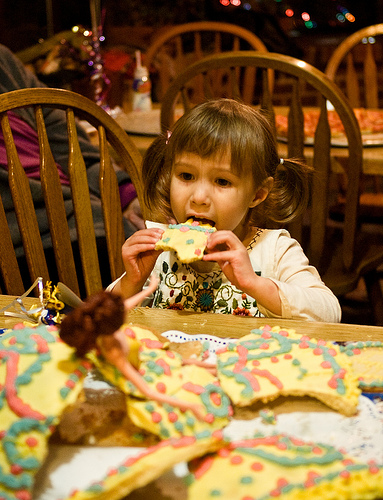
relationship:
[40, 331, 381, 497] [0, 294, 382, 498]
cloth on table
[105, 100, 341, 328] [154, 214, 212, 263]
girl eating cookie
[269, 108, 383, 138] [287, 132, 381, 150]
pizza on platter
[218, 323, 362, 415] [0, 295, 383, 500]
cookie on table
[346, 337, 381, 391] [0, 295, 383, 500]
cookie on table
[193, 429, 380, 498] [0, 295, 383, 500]
cookie on table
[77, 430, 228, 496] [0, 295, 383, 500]
cookie on table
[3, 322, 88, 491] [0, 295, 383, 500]
cookie on table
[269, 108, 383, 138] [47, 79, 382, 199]
pizza on table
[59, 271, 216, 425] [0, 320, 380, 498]
doll sitting on cookies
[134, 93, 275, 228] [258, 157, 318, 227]
girl with pig tail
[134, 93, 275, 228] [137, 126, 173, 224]
girl with pig tail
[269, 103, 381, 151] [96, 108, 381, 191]
pizza sitting on table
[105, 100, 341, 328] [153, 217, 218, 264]
girl sitting with food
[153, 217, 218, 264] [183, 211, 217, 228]
food to her mouth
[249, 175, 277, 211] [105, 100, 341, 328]
left ear of girl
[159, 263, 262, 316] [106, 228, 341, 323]
design on front of shirt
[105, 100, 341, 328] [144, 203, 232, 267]
girl eating cookie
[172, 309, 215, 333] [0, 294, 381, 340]
crumbs on table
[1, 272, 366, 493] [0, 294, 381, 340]
crumbs on table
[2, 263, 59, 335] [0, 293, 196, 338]
ribbon on table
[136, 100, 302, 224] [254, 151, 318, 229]
hair in pig tail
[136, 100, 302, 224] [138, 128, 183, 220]
hair in pig tail